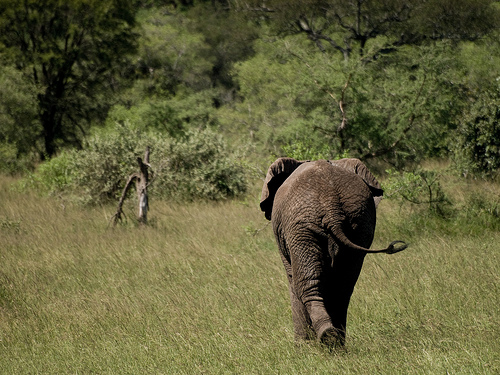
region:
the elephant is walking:
[220, 101, 373, 372]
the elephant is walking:
[260, 144, 410, 332]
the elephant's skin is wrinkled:
[280, 178, 319, 240]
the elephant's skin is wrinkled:
[316, 186, 368, 235]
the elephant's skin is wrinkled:
[273, 191, 335, 288]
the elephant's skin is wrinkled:
[288, 182, 400, 369]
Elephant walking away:
[257, 148, 387, 338]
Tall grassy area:
[6, 203, 496, 370]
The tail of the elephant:
[331, 225, 411, 261]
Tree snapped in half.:
[112, 144, 161, 226]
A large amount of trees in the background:
[1, 0, 496, 178]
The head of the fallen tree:
[38, 119, 255, 199]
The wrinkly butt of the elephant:
[289, 162, 373, 298]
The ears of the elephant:
[253, 147, 380, 221]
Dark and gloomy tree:
[0, 7, 142, 148]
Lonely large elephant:
[263, 151, 414, 343]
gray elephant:
[243, 143, 383, 353]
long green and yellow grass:
[21, 203, 56, 245]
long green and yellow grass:
[91, 244, 125, 268]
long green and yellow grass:
[196, 227, 230, 267]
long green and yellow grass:
[204, 286, 242, 320]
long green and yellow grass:
[231, 309, 279, 353]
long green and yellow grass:
[137, 290, 207, 328]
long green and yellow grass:
[96, 287, 147, 321]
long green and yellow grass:
[44, 281, 91, 311]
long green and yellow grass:
[386, 260, 467, 327]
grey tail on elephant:
[313, 187, 443, 268]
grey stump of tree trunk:
[125, 161, 189, 225]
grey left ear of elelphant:
[248, 150, 307, 211]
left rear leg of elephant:
[288, 240, 342, 374]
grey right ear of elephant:
[332, 143, 398, 200]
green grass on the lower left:
[36, 262, 136, 363]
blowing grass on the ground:
[159, 215, 227, 266]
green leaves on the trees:
[163, 39, 230, 111]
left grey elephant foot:
[306, 309, 347, 356]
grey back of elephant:
[293, 155, 375, 205]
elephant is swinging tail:
[299, 166, 396, 269]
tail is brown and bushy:
[340, 234, 420, 280]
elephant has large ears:
[242, 151, 395, 228]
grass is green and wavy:
[76, 255, 382, 373]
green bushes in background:
[47, 86, 495, 248]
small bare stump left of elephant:
[112, 154, 169, 225]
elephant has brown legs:
[261, 229, 350, 351]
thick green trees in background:
[56, 14, 436, 149]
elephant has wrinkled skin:
[274, 159, 383, 309]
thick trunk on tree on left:
[25, 77, 72, 164]